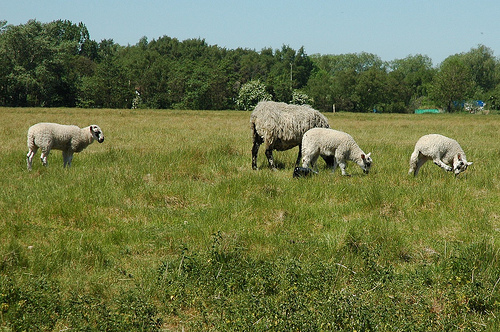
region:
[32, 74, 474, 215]
four sheep standing in a field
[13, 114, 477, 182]
three lambs standing in a field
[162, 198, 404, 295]
green grass of the field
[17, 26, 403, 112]
many trees growing on the edge of the field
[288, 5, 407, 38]
clear blue skies over the field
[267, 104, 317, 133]
grey fleece of the sheep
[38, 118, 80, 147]
white fleece of the lamb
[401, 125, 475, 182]
a lamb biting it's foot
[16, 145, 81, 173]
white legs of a lamb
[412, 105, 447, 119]
a green fence in the distance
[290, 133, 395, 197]
the sheep is eating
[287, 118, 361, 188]
the sheep is eating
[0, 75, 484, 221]
four sheep in the field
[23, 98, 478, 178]
four sheep and lambs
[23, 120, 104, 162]
a white lamb standing behind a sheep and two other lambs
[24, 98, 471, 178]
three lambs and a sheep in a pasture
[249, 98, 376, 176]
a sheep and a lamb eating grass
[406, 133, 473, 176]
a lamb trying to scratch the face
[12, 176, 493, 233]
green and brown grass on the ground in the pasture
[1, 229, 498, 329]
green weeds on the ground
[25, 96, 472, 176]
a sheep and three lambs in a green field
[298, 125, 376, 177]
a lamb grazing in a pasture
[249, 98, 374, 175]
a sheep standing beside a lamb eating grass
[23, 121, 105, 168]
sheep standing alone in a grassy field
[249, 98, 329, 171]
large wooly sheep standing next to another sheep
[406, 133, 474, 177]
sheep with back leg raised on the ground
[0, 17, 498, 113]
grove of trees in line behind sheep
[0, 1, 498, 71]
sky is blue and cloudless above trees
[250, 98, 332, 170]
largest sheep is in need of shearing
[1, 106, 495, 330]
grassy and weedy green pasture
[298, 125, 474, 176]
two small sheep looking down while grazing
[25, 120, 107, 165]
sheep facing and looking to the right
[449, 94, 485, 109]
blue structure far in distance in trees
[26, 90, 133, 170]
White sheep in the field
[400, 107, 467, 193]
White sheep in the field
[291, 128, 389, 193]
White sheep in the field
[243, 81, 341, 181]
White sheep in the field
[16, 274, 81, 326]
Small patch of green grass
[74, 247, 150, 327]
Small patch of green grass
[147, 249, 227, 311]
Small patch of green grass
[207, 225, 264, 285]
Small patch of green grass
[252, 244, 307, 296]
Small patch of green grass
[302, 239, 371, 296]
Small patch of green grass